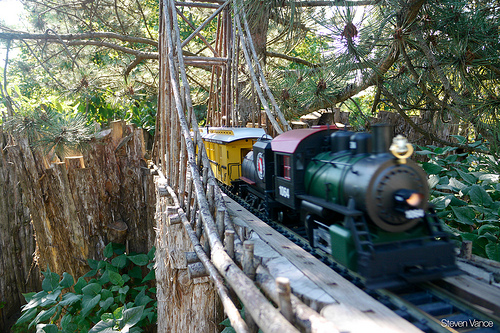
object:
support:
[154, 199, 218, 333]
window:
[276, 153, 291, 180]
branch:
[0, 33, 158, 78]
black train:
[190, 128, 462, 289]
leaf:
[127, 253, 149, 267]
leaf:
[58, 272, 73, 289]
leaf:
[468, 184, 494, 205]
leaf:
[115, 106, 130, 117]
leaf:
[59, 290, 83, 306]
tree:
[265, 0, 500, 152]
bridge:
[153, 0, 500, 333]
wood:
[271, 235, 390, 323]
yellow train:
[186, 126, 272, 186]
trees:
[0, 0, 500, 155]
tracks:
[395, 282, 465, 320]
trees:
[44, 73, 159, 144]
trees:
[190, 52, 422, 121]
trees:
[0, 0, 211, 142]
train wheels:
[273, 212, 313, 240]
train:
[305, 125, 455, 264]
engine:
[303, 131, 432, 233]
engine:
[363, 160, 431, 231]